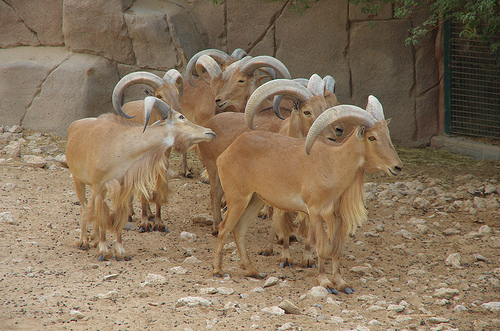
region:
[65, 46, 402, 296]
the herd of goats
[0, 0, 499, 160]
the walls of the animal enclosure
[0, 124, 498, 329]
the dirt on the ground of the animal enclosure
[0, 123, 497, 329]
the rocks on the ground of the animal enclosure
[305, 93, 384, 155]
the horns on the goat's head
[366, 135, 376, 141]
the eye on the goat's face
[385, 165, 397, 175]
the mouth on the goat's face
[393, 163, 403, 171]
the nose on the goat's face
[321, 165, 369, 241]
the long hair on the goat's body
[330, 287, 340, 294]
the claw on the goat's foot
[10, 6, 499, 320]
the animals are in an enclosure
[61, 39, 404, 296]
a herd of mountain goats are in a pen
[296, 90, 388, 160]
the mountain goat has curved horns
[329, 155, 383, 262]
the goat has a hairy chest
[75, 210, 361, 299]
black split hooves are on the goats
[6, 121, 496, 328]
rocks are scattered around the pen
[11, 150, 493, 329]
black pellets are dropped in the pen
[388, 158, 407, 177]
the mountain goats nose is black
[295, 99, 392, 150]
the mountain goats eyes are black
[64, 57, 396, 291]
the goats have brown coats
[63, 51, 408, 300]
seven goats all together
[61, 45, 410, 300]
seven goats standing on the ground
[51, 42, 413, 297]
seven goats with horns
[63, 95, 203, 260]
goat with its head turned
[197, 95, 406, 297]
goat leading the rest of the herd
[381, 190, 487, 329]
lots of rocks on the ground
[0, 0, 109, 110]
rock wall behind the goats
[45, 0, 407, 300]
goats are in front of the rock wall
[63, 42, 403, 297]
rocks are underneath the goats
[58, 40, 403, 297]
the goats are tan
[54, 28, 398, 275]
group of animals standing together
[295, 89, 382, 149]
horns of rams standing together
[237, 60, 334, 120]
large horns on a aram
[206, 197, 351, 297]
short brown legs of ram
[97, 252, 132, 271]
small black hooves of ram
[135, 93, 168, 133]
grey and white curve dears of ram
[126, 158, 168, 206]
dangling hair on front of ram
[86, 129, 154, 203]
brown fur coat on ram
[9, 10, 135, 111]
rock wall behind rams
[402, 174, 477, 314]
small rocks and dirt on ground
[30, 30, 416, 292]
8 mountain goats with light tan fur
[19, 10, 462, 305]
photograph taken at a zoo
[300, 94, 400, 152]
two large horns on goats head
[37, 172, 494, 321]
ground covered with small rocks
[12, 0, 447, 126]
wall made from large rocks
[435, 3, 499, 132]
metal fencing off to right side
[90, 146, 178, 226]
long hair hanging down front of goat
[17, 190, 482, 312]
ground covered with sand and rocks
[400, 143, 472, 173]
yellow straw hay on the ground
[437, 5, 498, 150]
fenced doorway